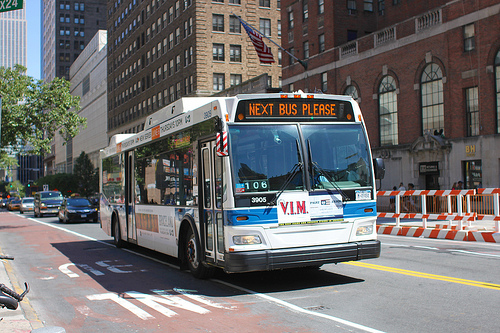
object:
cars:
[17, 196, 35, 214]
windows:
[208, 42, 227, 59]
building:
[168, 12, 224, 80]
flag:
[238, 17, 276, 64]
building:
[277, 0, 499, 213]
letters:
[58, 261, 102, 280]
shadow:
[48, 238, 366, 297]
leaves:
[60, 140, 67, 145]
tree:
[0, 62, 88, 193]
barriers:
[375, 188, 499, 242]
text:
[245, 100, 337, 117]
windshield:
[231, 125, 373, 189]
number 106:
[245, 179, 270, 192]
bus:
[93, 84, 384, 287]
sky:
[18, 26, 49, 72]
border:
[378, 195, 494, 215]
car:
[52, 192, 97, 224]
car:
[17, 191, 32, 213]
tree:
[70, 148, 95, 199]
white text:
[51, 260, 234, 318]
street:
[2, 205, 499, 332]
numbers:
[261, 180, 269, 190]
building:
[48, 31, 111, 194]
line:
[356, 262, 500, 292]